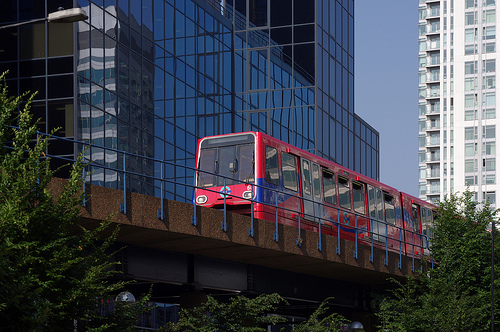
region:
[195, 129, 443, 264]
an inner city commuter train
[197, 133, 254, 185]
the front windshield of the front car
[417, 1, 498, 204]
a condominium apartment building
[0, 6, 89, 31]
a street light over the train tracks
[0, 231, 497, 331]
trees below the train overpass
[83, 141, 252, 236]
blue safety rails on the overpass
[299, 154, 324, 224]
side doors on the passenger train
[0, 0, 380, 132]
a commercial building with a glass wall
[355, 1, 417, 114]
blue sky without any clouds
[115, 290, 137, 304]
a white street light dome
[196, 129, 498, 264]
Red train.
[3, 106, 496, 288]
Train crossing over a bridge.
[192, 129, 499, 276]
Red train with blue trim.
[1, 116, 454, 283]
Bridge with blue rails.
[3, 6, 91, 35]
Overhead light.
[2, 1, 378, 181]
Glass building.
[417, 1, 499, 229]
White high rise building.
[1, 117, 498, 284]
Red train traveling across a bridge.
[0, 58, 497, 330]
Leafy green trees surrounding the bridge.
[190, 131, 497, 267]
Passenger train with many windows.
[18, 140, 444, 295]
an elevated train track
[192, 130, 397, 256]
a red train car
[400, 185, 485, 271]
a red train car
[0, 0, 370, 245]
a tall reflective building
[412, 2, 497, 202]
a tall white building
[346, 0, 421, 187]
a deep blue sky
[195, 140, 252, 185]
a train's front windshield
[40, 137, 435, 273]
blue metal railing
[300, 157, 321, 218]
train entrance exit doors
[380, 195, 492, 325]
rop of a tall green tree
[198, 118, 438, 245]
red and blure train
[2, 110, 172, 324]
a large green tree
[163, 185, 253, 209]
two head lights on train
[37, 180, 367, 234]
blue metal rail of bridge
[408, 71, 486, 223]
tall white building with windows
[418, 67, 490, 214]
tall white building with a balcony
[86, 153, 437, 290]
red and blue train on bridge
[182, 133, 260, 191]
front window of atrain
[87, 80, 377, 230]
building with lots of windows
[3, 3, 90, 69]
light pole and light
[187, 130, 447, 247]
Train is red color.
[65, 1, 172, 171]
Reflection is seen in building glass.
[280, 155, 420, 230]
Windows are attached to the sides of the train.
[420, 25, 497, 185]
Building is white color.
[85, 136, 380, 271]
Train is on bridge.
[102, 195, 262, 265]
Bridge is brown color.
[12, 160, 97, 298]
Leaves are green color.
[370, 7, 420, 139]
Sky is blue color.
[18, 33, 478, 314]
Day time picture.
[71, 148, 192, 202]
Rail is grey color.